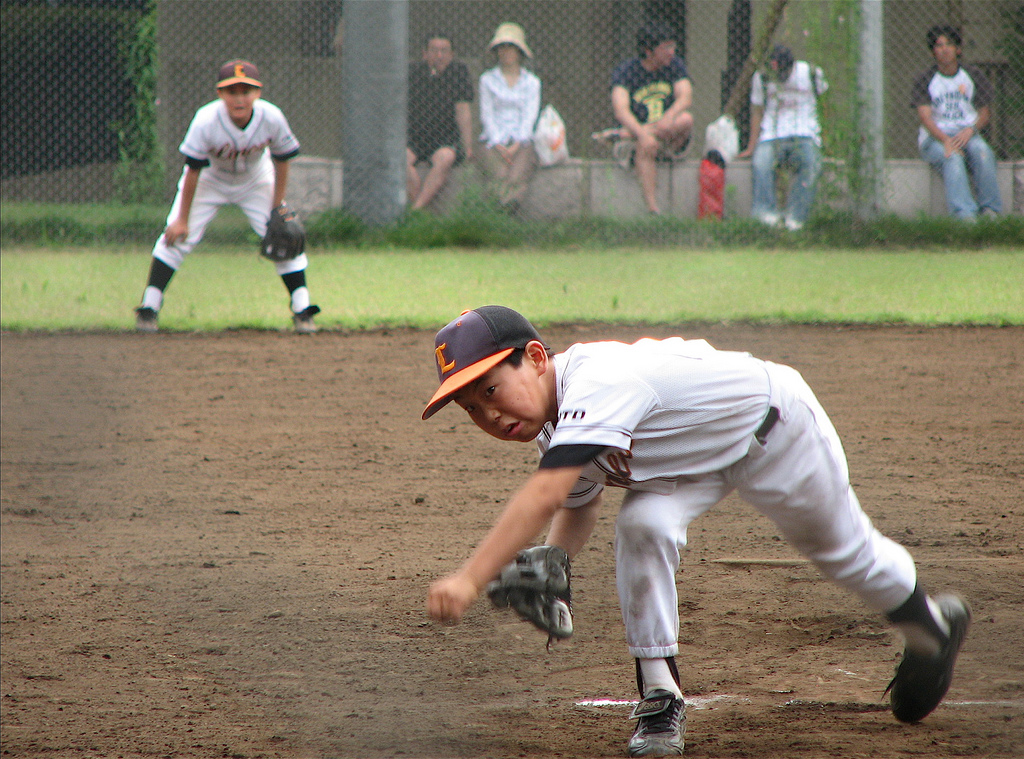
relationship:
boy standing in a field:
[420, 303, 974, 757] [0, 232, 1020, 757]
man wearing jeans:
[914, 24, 1007, 226] [919, 134, 1006, 215]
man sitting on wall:
[914, 24, 1007, 226] [277, 150, 1020, 226]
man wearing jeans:
[747, 50, 836, 234] [749, 142, 829, 225]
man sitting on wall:
[747, 50, 836, 234] [277, 150, 1020, 226]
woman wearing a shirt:
[474, 17, 544, 224] [474, 64, 542, 143]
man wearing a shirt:
[405, 33, 477, 221] [407, 63, 471, 150]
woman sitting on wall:
[474, 17, 544, 224] [277, 150, 1020, 226]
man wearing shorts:
[405, 33, 477, 221] [401, 130, 468, 165]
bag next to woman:
[533, 105, 571, 169] [474, 17, 544, 224]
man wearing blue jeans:
[914, 24, 1007, 226] [919, 134, 1006, 215]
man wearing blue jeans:
[747, 50, 836, 234] [749, 142, 829, 225]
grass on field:
[2, 238, 1023, 331] [0, 232, 1020, 757]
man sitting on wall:
[405, 33, 477, 221] [277, 150, 1020, 226]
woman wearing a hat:
[474, 17, 544, 224] [487, 21, 532, 62]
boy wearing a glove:
[420, 303, 974, 757] [494, 542, 577, 642]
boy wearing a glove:
[130, 54, 322, 332] [260, 206, 306, 266]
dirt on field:
[2, 327, 1021, 755] [0, 232, 1020, 757]